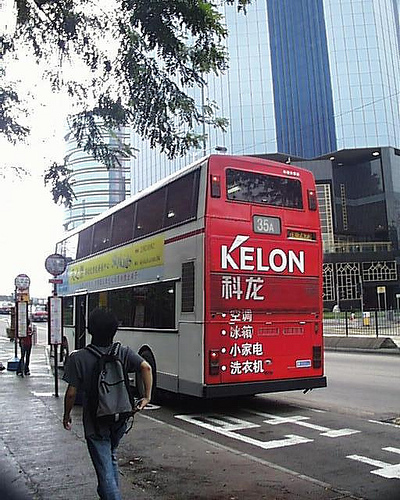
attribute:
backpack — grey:
[95, 355, 132, 422]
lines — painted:
[171, 403, 369, 468]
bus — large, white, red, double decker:
[51, 154, 325, 401]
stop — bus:
[15, 256, 64, 396]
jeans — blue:
[82, 420, 131, 496]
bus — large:
[21, 138, 326, 454]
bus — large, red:
[47, 141, 349, 433]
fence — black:
[311, 300, 399, 341]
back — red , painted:
[200, 150, 338, 394]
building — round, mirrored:
[36, 14, 371, 329]